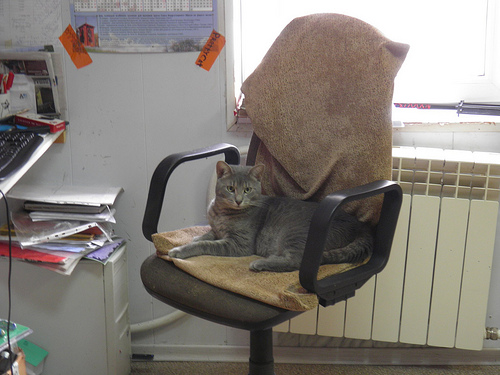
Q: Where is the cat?
A: On the chair.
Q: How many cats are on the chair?
A: One.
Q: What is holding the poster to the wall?
A: Tape.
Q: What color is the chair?
A: Black.